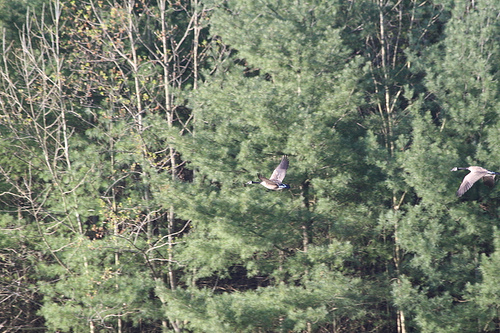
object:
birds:
[245, 153, 499, 201]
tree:
[410, 11, 500, 333]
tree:
[132, 0, 392, 332]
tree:
[29, 127, 164, 332]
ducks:
[245, 155, 500, 199]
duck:
[248, 155, 292, 194]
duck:
[451, 162, 497, 200]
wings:
[257, 174, 283, 190]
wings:
[455, 171, 484, 197]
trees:
[0, 0, 499, 332]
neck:
[456, 162, 467, 173]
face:
[449, 164, 459, 176]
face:
[245, 177, 253, 187]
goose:
[241, 157, 294, 198]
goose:
[449, 159, 496, 199]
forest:
[70, 3, 223, 332]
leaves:
[101, 53, 153, 89]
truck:
[298, 168, 319, 332]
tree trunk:
[373, 23, 411, 332]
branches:
[3, 9, 109, 128]